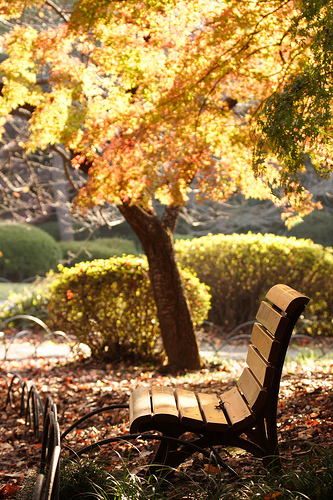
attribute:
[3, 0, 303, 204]
leaves — yellow, orange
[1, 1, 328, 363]
tree — leafless, brown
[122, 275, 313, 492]
bench — brown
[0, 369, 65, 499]
fence — small, black, wire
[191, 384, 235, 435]
wood — brown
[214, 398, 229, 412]
object — small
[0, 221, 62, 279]
shrub — round, green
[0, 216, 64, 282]
bush — trimmed, rounded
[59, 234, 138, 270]
bush — trimmed, rounded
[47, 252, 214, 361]
bush — trimmed, rounded, green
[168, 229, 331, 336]
bush — trimmed, rounded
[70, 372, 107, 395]
leaves — dry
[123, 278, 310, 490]
park bench — small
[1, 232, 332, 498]
leaves — dry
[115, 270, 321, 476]
bench — brown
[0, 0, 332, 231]
leaves — colored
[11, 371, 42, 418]
gate — black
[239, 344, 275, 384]
slat — wood, brown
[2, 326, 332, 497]
leaves — dry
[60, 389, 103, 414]
orange leaves — brown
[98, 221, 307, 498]
bench — wooden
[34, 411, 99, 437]
wire fence — loop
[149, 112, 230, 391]
leaves — green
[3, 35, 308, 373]
tree — tall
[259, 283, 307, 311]
slat — brown, wood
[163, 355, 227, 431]
slat — brown, wood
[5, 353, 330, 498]
leaves — bundled